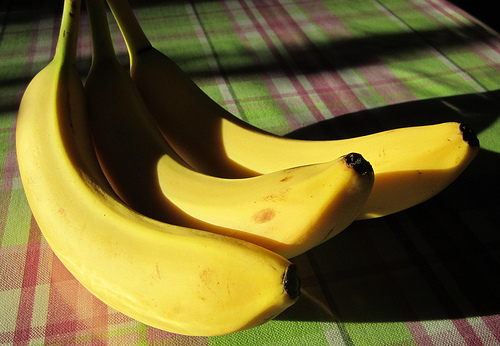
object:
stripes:
[335, 2, 497, 130]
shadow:
[62, 50, 263, 219]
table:
[123, 5, 496, 139]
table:
[4, 4, 77, 344]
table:
[69, 281, 499, 346]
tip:
[340, 152, 373, 175]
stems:
[84, 1, 118, 63]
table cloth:
[259, 31, 390, 71]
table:
[0, 2, 497, 346]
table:
[298, 234, 498, 344]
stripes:
[0, 214, 42, 344]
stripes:
[380, 218, 480, 346]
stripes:
[1, 1, 47, 68]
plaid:
[0, 0, 499, 346]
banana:
[14, 0, 300, 338]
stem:
[51, 2, 80, 57]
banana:
[84, 1, 375, 259]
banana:
[108, 0, 480, 221]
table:
[7, 6, 497, 88]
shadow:
[271, 147, 499, 324]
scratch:
[249, 209, 275, 224]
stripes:
[330, 312, 353, 346]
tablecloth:
[2, 291, 57, 346]